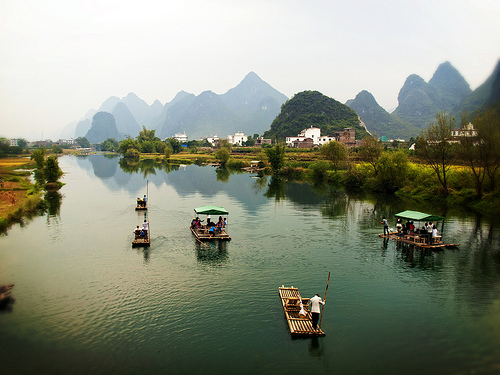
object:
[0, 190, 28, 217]
dirt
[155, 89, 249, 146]
mountain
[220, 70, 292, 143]
mountain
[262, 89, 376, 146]
mountain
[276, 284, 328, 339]
boat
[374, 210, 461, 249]
boat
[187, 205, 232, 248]
boat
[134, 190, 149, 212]
boat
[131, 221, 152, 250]
boat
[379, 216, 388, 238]
man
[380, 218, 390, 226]
shirt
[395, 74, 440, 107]
mountain peak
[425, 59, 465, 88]
mountain peak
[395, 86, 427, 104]
mountain peak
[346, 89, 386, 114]
mountain peak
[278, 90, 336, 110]
mountain peak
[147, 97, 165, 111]
mountain peak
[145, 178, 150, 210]
stick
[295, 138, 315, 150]
house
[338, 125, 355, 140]
house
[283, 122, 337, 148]
house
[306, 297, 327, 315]
shirt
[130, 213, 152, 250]
boat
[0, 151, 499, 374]
river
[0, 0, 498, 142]
gray sky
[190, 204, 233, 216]
green covering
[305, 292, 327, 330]
man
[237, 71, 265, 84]
peak